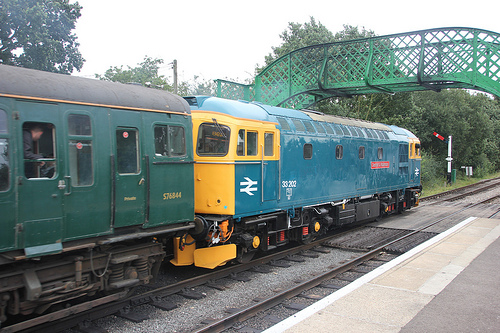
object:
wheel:
[235, 228, 257, 263]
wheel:
[297, 213, 318, 240]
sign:
[428, 130, 449, 144]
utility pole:
[170, 55, 180, 91]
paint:
[209, 163, 231, 200]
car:
[0, 61, 423, 332]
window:
[20, 120, 59, 180]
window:
[198, 125, 228, 153]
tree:
[0, 0, 86, 75]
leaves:
[0, 0, 85, 75]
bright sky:
[62, 0, 497, 98]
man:
[22, 121, 45, 164]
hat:
[30, 125, 42, 132]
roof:
[1, 61, 192, 115]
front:
[0, 63, 193, 332]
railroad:
[0, 178, 499, 332]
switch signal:
[432, 127, 457, 182]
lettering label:
[367, 160, 400, 174]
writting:
[164, 190, 184, 203]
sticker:
[120, 128, 130, 140]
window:
[116, 126, 141, 175]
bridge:
[212, 27, 498, 111]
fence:
[252, 26, 499, 108]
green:
[308, 24, 403, 123]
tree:
[430, 87, 499, 158]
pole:
[445, 124, 454, 183]